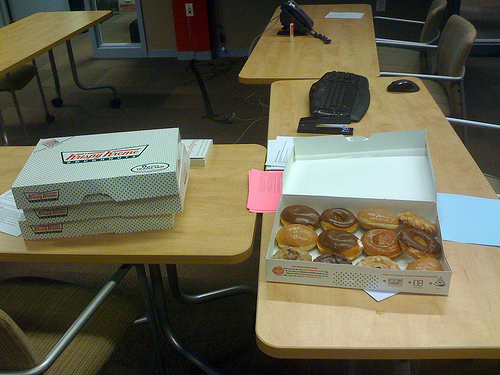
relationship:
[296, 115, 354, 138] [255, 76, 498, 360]
stapler on table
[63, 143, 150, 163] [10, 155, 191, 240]
logo on box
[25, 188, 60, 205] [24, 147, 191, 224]
logo on box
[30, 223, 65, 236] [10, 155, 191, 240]
logo on box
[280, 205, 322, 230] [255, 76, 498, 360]
doughnut on table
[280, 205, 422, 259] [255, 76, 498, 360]
doughnut on table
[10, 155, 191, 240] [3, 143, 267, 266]
box on table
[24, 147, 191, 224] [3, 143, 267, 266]
box on table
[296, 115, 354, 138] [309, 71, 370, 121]
stapler next to keyboard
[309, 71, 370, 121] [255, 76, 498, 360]
keyboard on table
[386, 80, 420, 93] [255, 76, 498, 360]
mouse on table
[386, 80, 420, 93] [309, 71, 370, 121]
mouse beside keyboard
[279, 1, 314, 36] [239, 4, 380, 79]
phone on table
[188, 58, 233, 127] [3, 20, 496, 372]
tape on floor